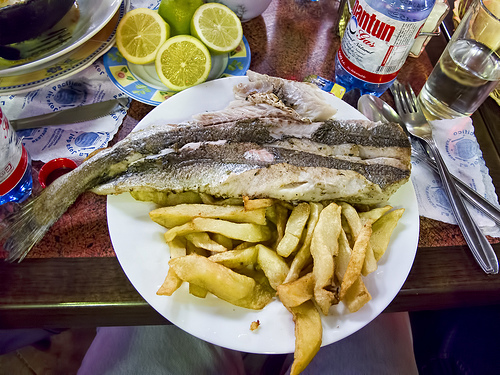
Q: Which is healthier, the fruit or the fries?
A: The fruit is healthier than the fries.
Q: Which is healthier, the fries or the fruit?
A: The fruit is healthier than the fries.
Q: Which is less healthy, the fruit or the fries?
A: The fries is less healthy than the fruit.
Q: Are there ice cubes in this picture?
A: No, there are no ice cubes.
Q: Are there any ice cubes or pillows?
A: No, there are no ice cubes or pillows.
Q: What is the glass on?
A: The glass is on the table.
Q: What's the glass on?
A: The glass is on the table.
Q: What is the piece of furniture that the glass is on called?
A: The piece of furniture is a table.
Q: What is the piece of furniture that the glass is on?
A: The piece of furniture is a table.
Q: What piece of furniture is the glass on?
A: The glass is on the table.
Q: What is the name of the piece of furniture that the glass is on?
A: The piece of furniture is a table.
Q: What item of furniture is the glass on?
A: The glass is on the table.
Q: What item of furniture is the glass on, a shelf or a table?
A: The glass is on a table.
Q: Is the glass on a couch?
A: No, the glass is on the table.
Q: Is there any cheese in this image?
A: No, there is no cheese.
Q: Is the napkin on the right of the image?
A: Yes, the napkin is on the right of the image.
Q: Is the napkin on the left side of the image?
A: No, the napkin is on the right of the image.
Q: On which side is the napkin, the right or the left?
A: The napkin is on the right of the image.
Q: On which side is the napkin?
A: The napkin is on the right of the image.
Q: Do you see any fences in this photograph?
A: No, there are no fences.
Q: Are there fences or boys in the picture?
A: No, there are no fences or boys.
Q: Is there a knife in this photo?
A: Yes, there is a knife.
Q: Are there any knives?
A: Yes, there is a knife.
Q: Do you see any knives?
A: Yes, there is a knife.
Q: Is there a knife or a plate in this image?
A: Yes, there is a knife.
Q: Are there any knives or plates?
A: Yes, there is a knife.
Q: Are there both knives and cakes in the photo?
A: No, there is a knife but no cakes.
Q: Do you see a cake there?
A: No, there are no cakes.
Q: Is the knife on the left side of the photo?
A: Yes, the knife is on the left of the image.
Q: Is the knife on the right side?
A: No, the knife is on the left of the image.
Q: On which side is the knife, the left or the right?
A: The knife is on the left of the image.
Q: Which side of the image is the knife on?
A: The knife is on the left of the image.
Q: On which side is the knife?
A: The knife is on the left of the image.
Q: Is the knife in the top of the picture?
A: Yes, the knife is in the top of the image.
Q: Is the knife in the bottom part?
A: No, the knife is in the top of the image.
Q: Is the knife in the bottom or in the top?
A: The knife is in the top of the image.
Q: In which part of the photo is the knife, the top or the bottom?
A: The knife is in the top of the image.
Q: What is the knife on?
A: The knife is on the table.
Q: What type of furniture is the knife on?
A: The knife is on the table.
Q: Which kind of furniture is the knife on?
A: The knife is on the table.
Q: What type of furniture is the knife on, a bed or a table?
A: The knife is on a table.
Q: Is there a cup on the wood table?
A: No, there is a knife on the table.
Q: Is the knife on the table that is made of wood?
A: Yes, the knife is on the table.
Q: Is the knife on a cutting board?
A: No, the knife is on the table.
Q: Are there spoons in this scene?
A: Yes, there is a spoon.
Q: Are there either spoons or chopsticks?
A: Yes, there is a spoon.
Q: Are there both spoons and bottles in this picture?
A: Yes, there are both a spoon and a bottle.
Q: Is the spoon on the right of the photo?
A: Yes, the spoon is on the right of the image.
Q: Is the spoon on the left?
A: No, the spoon is on the right of the image.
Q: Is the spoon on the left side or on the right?
A: The spoon is on the right of the image.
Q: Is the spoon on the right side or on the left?
A: The spoon is on the right of the image.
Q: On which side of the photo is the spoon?
A: The spoon is on the right of the image.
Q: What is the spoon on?
A: The spoon is on the table.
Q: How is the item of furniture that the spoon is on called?
A: The piece of furniture is a table.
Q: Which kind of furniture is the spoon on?
A: The spoon is on the table.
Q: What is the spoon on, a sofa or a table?
A: The spoon is on a table.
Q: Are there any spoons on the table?
A: Yes, there is a spoon on the table.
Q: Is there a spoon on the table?
A: Yes, there is a spoon on the table.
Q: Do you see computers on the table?
A: No, there is a spoon on the table.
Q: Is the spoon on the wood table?
A: Yes, the spoon is on the table.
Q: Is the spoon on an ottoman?
A: No, the spoon is on the table.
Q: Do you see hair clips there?
A: No, there are no hair clips.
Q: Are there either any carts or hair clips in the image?
A: No, there are no hair clips or carts.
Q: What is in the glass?
A: The liquid is in the glass.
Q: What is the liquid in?
A: The liquid is in the glass.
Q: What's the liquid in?
A: The liquid is in the glass.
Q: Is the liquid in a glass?
A: Yes, the liquid is in a glass.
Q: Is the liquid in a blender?
A: No, the liquid is in a glass.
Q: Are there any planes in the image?
A: No, there are no planes.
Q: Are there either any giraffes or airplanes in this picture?
A: No, there are no airplanes or giraffes.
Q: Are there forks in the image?
A: Yes, there is a fork.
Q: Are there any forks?
A: Yes, there is a fork.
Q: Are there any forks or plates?
A: Yes, there is a fork.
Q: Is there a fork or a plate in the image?
A: Yes, there is a fork.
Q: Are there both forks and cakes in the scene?
A: No, there is a fork but no cakes.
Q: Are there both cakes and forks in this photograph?
A: No, there is a fork but no cakes.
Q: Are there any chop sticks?
A: No, there are no chop sticks.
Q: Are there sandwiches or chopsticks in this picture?
A: No, there are no chopsticks or sandwiches.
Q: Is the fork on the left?
A: No, the fork is on the right of the image.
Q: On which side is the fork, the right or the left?
A: The fork is on the right of the image.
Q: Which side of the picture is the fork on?
A: The fork is on the right of the image.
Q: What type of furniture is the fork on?
A: The fork is on the table.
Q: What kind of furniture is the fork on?
A: The fork is on the table.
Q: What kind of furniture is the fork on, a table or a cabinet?
A: The fork is on a table.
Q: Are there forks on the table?
A: Yes, there is a fork on the table.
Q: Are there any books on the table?
A: No, there is a fork on the table.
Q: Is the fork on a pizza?
A: No, the fork is on the table.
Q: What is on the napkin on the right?
A: The fork is on the napkin.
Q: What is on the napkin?
A: The fork is on the napkin.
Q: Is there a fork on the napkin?
A: Yes, there is a fork on the napkin.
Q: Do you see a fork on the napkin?
A: Yes, there is a fork on the napkin.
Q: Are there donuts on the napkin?
A: No, there is a fork on the napkin.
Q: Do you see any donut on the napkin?
A: No, there is a fork on the napkin.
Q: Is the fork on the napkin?
A: Yes, the fork is on the napkin.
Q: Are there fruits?
A: Yes, there is a fruit.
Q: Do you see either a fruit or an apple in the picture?
A: Yes, there is a fruit.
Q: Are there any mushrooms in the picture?
A: No, there are no mushrooms.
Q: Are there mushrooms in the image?
A: No, there are no mushrooms.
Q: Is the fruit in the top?
A: Yes, the fruit is in the top of the image.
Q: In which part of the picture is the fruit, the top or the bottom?
A: The fruit is in the top of the image.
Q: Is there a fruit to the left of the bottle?
A: Yes, there is a fruit to the left of the bottle.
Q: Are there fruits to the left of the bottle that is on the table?
A: Yes, there is a fruit to the left of the bottle.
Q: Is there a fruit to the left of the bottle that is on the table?
A: Yes, there is a fruit to the left of the bottle.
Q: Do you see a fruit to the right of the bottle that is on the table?
A: No, the fruit is to the left of the bottle.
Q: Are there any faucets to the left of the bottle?
A: No, there is a fruit to the left of the bottle.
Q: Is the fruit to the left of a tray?
A: No, the fruit is to the left of the bottle.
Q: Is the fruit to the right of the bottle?
A: No, the fruit is to the left of the bottle.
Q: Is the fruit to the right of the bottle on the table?
A: No, the fruit is to the left of the bottle.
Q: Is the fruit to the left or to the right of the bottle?
A: The fruit is to the left of the bottle.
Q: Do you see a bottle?
A: Yes, there is a bottle.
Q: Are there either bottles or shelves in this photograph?
A: Yes, there is a bottle.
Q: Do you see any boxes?
A: No, there are no boxes.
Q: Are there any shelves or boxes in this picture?
A: No, there are no boxes or shelves.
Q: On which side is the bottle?
A: The bottle is on the right of the image.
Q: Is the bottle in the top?
A: Yes, the bottle is in the top of the image.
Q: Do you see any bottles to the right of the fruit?
A: Yes, there is a bottle to the right of the fruit.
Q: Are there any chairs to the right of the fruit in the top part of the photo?
A: No, there is a bottle to the right of the fruit.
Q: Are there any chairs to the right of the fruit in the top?
A: No, there is a bottle to the right of the fruit.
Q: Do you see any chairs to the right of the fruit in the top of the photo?
A: No, there is a bottle to the right of the fruit.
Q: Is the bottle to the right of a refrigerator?
A: No, the bottle is to the right of a fruit.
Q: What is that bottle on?
A: The bottle is on the table.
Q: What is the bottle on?
A: The bottle is on the table.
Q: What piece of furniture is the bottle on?
A: The bottle is on the table.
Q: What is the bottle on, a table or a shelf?
A: The bottle is on a table.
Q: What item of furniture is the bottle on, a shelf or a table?
A: The bottle is on a table.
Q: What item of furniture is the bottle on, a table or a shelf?
A: The bottle is on a table.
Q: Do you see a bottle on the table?
A: Yes, there is a bottle on the table.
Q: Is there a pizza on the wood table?
A: No, there is a bottle on the table.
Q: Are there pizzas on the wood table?
A: No, there is a bottle on the table.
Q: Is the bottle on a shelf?
A: No, the bottle is on the table.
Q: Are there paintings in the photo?
A: No, there are no paintings.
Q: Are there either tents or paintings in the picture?
A: No, there are no paintings or tents.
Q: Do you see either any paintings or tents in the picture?
A: No, there are no paintings or tents.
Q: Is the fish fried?
A: Yes, the fish is fried.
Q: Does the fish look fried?
A: Yes, the fish is fried.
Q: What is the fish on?
A: The fish is on the plate.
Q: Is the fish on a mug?
A: No, the fish is on the plate.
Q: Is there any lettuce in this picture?
A: No, there is no lettuce.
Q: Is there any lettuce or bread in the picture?
A: No, there are no lettuce or breads.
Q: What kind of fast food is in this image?
A: The fast food is fries.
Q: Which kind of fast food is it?
A: The food is fries.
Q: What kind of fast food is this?
A: These are fries.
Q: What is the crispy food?
A: The food is fries.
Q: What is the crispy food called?
A: The food is fries.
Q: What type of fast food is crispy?
A: The fast food is fries.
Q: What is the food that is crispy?
A: The food is fries.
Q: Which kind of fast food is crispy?
A: The fast food is fries.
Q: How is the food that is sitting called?
A: The food is fries.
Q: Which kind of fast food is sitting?
A: The fast food is fries.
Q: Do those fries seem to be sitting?
A: Yes, the fries are sitting.